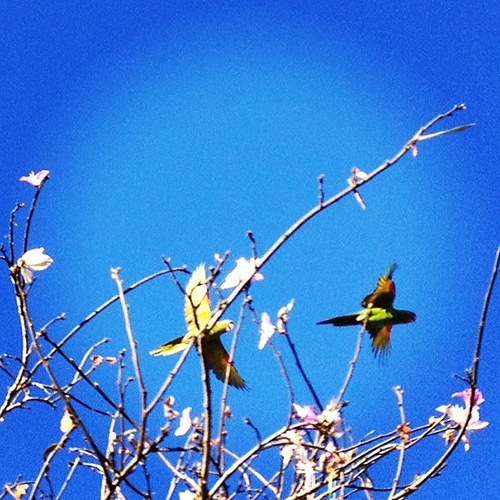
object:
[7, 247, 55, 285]
flowers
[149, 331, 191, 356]
tail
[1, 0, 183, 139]
sky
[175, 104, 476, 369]
branch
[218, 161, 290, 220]
sky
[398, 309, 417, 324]
head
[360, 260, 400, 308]
wing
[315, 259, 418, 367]
bird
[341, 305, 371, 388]
branch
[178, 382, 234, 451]
branch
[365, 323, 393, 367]
feathers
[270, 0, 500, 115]
sky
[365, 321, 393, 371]
wing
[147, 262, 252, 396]
bird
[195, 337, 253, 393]
wing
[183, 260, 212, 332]
wing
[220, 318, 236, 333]
head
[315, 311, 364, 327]
tail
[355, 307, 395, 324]
chest feathers